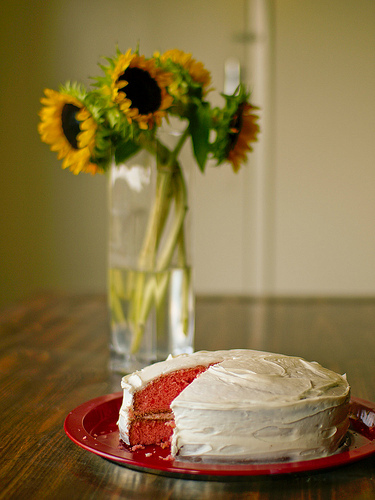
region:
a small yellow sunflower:
[32, 76, 110, 168]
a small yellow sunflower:
[98, 46, 168, 124]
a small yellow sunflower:
[153, 45, 209, 91]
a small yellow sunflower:
[217, 90, 258, 171]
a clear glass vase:
[103, 121, 194, 367]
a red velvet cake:
[118, 345, 349, 460]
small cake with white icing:
[119, 348, 343, 457]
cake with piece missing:
[117, 349, 350, 462]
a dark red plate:
[64, 384, 372, 482]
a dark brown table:
[6, 289, 372, 496]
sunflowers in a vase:
[38, 47, 257, 370]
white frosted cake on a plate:
[62, 347, 373, 480]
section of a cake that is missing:
[129, 362, 217, 446]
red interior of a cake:
[135, 369, 203, 446]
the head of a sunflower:
[39, 85, 104, 171]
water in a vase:
[107, 264, 195, 372]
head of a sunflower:
[104, 56, 168, 128]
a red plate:
[71, 389, 374, 477]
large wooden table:
[2, 286, 374, 498]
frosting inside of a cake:
[136, 413, 175, 422]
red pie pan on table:
[68, 384, 127, 462]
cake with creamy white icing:
[216, 381, 311, 455]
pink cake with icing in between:
[137, 373, 169, 445]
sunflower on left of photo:
[39, 69, 95, 164]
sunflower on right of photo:
[216, 61, 272, 186]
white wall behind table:
[276, 45, 331, 191]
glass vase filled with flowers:
[104, 167, 225, 335]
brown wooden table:
[17, 311, 66, 394]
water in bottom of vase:
[113, 260, 215, 364]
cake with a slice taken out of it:
[124, 350, 246, 465]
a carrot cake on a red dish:
[52, 340, 373, 483]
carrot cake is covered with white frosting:
[112, 342, 358, 471]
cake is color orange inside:
[128, 363, 184, 446]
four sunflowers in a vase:
[28, 37, 270, 360]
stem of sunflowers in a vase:
[105, 142, 211, 369]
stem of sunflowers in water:
[103, 261, 198, 370]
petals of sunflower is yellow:
[32, 67, 111, 187]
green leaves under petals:
[32, 77, 116, 178]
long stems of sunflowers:
[119, 130, 196, 352]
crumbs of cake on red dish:
[121, 441, 169, 462]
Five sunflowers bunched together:
[44, 57, 254, 178]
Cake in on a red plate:
[76, 343, 374, 469]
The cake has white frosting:
[124, 351, 346, 455]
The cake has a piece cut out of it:
[119, 347, 353, 457]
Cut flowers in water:
[66, 79, 215, 364]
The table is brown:
[25, 292, 102, 391]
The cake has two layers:
[117, 365, 225, 463]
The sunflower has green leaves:
[107, 58, 169, 128]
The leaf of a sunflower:
[188, 104, 211, 171]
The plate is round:
[56, 356, 371, 468]